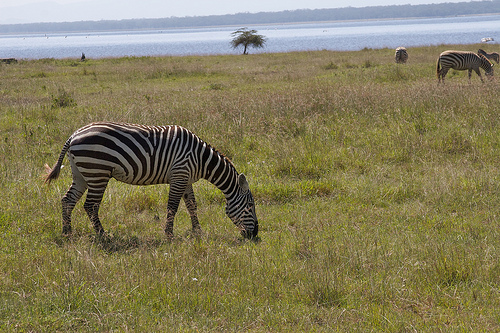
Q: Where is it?
A: This is at the field.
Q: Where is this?
A: This is at the field.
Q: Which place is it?
A: It is a field.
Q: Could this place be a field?
A: Yes, it is a field.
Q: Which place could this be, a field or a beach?
A: It is a field.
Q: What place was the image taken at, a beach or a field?
A: It was taken at a field.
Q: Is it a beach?
A: No, it is a field.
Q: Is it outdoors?
A: Yes, it is outdoors.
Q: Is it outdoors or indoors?
A: It is outdoors.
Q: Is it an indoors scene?
A: No, it is outdoors.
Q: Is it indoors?
A: No, it is outdoors.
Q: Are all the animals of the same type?
A: Yes, all the animals are zebras.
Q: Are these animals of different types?
A: No, all the animals are zebras.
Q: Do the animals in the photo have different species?
A: No, all the animals are zebras.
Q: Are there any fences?
A: No, there are no fences.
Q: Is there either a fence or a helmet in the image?
A: No, there are no fences or helmets.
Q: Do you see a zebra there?
A: Yes, there is a zebra.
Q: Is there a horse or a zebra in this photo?
A: Yes, there is a zebra.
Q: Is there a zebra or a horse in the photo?
A: Yes, there is a zebra.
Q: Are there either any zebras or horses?
A: Yes, there is a zebra.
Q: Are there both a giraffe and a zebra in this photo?
A: No, there is a zebra but no giraffes.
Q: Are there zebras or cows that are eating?
A: Yes, the zebra is eating.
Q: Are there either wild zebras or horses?
A: Yes, there is a wild zebra.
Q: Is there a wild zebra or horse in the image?
A: Yes, there is a wild zebra.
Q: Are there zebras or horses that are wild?
A: Yes, the zebra is wild.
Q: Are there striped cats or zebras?
A: Yes, there is a striped zebra.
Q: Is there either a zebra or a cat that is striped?
A: Yes, the zebra is striped.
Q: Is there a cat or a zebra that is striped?
A: Yes, the zebra is striped.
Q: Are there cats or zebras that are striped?
A: Yes, the zebra is striped.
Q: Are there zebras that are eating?
A: Yes, there is a zebra that is eating.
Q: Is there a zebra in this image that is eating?
A: Yes, there is a zebra that is eating.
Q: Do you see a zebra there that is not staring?
A: Yes, there is a zebra that is eating .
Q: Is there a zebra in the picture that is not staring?
A: Yes, there is a zebra that is eating.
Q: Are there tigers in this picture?
A: No, there are no tigers.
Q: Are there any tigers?
A: No, there are no tigers.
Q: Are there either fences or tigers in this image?
A: No, there are no tigers or fences.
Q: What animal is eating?
A: The animal is a zebra.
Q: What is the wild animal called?
A: The animal is a zebra.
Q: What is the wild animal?
A: The animal is a zebra.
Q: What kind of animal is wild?
A: The animal is a zebra.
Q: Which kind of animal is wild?
A: The animal is a zebra.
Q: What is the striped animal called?
A: The animal is a zebra.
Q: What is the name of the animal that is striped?
A: The animal is a zebra.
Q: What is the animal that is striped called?
A: The animal is a zebra.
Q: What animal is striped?
A: The animal is a zebra.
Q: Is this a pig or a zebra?
A: This is a zebra.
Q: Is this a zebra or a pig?
A: This is a zebra.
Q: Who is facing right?
A: The zebra is facing right.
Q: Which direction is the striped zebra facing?
A: The zebra is facing right.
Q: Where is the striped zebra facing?
A: The zebra is facing right.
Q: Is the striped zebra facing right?
A: Yes, the zebra is facing right.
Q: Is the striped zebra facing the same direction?
A: No, the zebra is facing right.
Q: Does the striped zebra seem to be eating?
A: Yes, the zebra is eating.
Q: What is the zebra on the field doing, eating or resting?
A: The zebra is eating.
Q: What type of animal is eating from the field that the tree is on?
A: The animal is a zebra.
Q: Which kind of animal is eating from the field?
A: The animal is a zebra.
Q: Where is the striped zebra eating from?
A: The zebra is eating from the field.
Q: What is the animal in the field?
A: The animal is a zebra.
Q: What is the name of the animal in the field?
A: The animal is a zebra.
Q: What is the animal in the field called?
A: The animal is a zebra.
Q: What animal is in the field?
A: The animal is a zebra.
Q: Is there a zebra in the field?
A: Yes, there is a zebra in the field.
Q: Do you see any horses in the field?
A: No, there is a zebra in the field.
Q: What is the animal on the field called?
A: The animal is a zebra.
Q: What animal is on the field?
A: The animal is a zebra.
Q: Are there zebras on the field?
A: Yes, there is a zebra on the field.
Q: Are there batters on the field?
A: No, there is a zebra on the field.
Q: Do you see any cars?
A: No, there are no cars.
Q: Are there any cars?
A: No, there are no cars.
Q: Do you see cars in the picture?
A: No, there are no cars.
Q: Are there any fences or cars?
A: No, there are no cars or fences.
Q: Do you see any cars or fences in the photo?
A: No, there are no cars or fences.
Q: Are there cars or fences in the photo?
A: No, there are no cars or fences.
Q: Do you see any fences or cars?
A: No, there are no cars or fences.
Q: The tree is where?
A: The tree is in the field.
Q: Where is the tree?
A: The tree is on the field.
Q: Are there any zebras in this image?
A: Yes, there is a zebra.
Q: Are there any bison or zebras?
A: Yes, there is a zebra.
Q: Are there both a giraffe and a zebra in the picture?
A: No, there is a zebra but no giraffes.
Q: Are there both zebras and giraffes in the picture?
A: No, there is a zebra but no giraffes.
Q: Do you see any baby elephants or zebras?
A: Yes, there is a baby zebra.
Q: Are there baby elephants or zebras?
A: Yes, there is a baby zebra.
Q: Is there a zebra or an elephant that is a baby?
A: Yes, the zebra is a baby.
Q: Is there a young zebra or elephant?
A: Yes, there is a young zebra.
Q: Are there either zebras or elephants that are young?
A: Yes, the zebra is young.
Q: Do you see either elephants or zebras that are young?
A: Yes, the zebra is young.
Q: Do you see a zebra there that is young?
A: Yes, there is a young zebra.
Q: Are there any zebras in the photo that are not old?
A: Yes, there is an young zebra.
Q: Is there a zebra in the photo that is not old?
A: Yes, there is an young zebra.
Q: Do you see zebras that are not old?
A: Yes, there is an young zebra.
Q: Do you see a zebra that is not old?
A: Yes, there is an young zebra.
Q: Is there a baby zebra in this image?
A: Yes, there is a baby zebra.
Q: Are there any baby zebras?
A: Yes, there is a baby zebra.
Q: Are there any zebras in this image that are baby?
A: Yes, there is a zebra that is a baby.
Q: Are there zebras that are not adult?
A: Yes, there is an baby zebra.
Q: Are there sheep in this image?
A: No, there are no sheep.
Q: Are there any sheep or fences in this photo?
A: No, there are no sheep or fences.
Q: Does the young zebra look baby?
A: Yes, the zebra is a baby.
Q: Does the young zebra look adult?
A: No, the zebra is a baby.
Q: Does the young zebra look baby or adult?
A: The zebra is a baby.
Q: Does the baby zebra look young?
A: Yes, the zebra is young.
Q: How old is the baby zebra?
A: The zebra is young.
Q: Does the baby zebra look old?
A: No, the zebra is young.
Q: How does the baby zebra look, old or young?
A: The zebra is young.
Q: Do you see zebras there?
A: Yes, there are zebras.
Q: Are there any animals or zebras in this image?
A: Yes, there are zebras.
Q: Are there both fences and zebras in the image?
A: No, there are zebras but no fences.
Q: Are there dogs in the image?
A: No, there are no dogs.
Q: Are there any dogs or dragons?
A: No, there are no dogs or dragons.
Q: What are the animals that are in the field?
A: The animals are zebras.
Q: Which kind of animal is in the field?
A: The animals are zebras.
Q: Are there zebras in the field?
A: Yes, there are zebras in the field.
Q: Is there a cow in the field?
A: No, there are zebras in the field.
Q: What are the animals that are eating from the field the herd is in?
A: The animals are zebras.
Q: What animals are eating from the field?
A: The animals are zebras.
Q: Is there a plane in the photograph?
A: No, there are no airplanes.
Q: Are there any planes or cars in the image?
A: No, there are no planes or cars.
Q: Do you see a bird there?
A: No, there are no birds.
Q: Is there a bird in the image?
A: No, there are no birds.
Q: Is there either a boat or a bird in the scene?
A: No, there are no birds or boats.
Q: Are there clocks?
A: No, there are no clocks.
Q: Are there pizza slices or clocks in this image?
A: No, there are no clocks or pizza slices.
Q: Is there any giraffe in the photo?
A: No, there are no giraffes.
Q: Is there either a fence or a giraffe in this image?
A: No, there are no giraffes or fences.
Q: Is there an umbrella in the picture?
A: No, there are no umbrellas.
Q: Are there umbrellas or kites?
A: No, there are no umbrellas or kites.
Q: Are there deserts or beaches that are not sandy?
A: No, there is a beach but it is sandy.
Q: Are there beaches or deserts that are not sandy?
A: No, there is a beach but it is sandy.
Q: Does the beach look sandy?
A: Yes, the beach is sandy.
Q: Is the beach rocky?
A: No, the beach is sandy.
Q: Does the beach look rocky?
A: No, the beach is sandy.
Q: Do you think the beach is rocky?
A: No, the beach is sandy.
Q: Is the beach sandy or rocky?
A: The beach is sandy.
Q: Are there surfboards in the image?
A: No, there are no surfboards.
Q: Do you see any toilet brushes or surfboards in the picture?
A: No, there are no surfboards or toilet brushes.